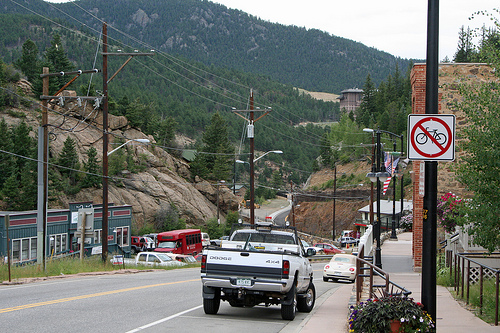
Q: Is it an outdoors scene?
A: Yes, it is outdoors.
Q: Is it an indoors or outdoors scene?
A: It is outdoors.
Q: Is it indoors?
A: No, it is outdoors.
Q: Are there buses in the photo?
A: Yes, there is a bus.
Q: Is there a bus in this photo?
A: Yes, there is a bus.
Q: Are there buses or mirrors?
A: Yes, there is a bus.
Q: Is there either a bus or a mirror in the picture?
A: Yes, there is a bus.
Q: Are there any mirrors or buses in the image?
A: Yes, there is a bus.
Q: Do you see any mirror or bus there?
A: Yes, there is a bus.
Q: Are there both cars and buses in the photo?
A: Yes, there are both a bus and a car.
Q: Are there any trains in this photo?
A: No, there are no trains.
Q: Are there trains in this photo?
A: No, there are no trains.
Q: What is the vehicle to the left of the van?
A: The vehicle is a bus.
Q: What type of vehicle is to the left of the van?
A: The vehicle is a bus.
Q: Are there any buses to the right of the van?
A: No, the bus is to the left of the van.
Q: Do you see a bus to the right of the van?
A: No, the bus is to the left of the van.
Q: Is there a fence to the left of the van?
A: No, there is a bus to the left of the van.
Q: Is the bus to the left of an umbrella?
A: No, the bus is to the left of a van.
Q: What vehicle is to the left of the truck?
A: The vehicle is a bus.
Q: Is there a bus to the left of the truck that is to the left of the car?
A: Yes, there is a bus to the left of the truck.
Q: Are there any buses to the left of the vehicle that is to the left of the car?
A: Yes, there is a bus to the left of the truck.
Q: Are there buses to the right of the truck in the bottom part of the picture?
A: No, the bus is to the left of the truck.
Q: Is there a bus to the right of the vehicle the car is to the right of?
A: No, the bus is to the left of the truck.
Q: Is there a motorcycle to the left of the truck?
A: No, there is a bus to the left of the truck.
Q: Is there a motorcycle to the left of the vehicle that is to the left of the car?
A: No, there is a bus to the left of the truck.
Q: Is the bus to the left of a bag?
A: No, the bus is to the left of the truck.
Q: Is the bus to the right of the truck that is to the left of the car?
A: No, the bus is to the left of the truck.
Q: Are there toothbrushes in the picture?
A: No, there are no toothbrushes.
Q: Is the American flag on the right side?
A: Yes, the American flag is on the right of the image.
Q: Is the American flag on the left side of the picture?
A: No, the American flag is on the right of the image.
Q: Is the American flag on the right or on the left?
A: The American flag is on the right of the image.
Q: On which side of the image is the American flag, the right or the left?
A: The American flag is on the right of the image.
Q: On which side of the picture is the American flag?
A: The American flag is on the right of the image.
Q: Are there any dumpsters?
A: No, there are no dumpsters.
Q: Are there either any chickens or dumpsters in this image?
A: No, there are no dumpsters or chickens.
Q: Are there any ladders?
A: No, there are no ladders.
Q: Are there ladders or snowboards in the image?
A: No, there are no ladders or snowboards.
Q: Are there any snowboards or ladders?
A: No, there are no ladders or snowboards.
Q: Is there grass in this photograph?
A: Yes, there is grass.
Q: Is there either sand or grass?
A: Yes, there is grass.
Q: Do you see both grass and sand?
A: No, there is grass but no sand.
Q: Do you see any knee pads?
A: No, there are no knee pads.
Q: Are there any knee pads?
A: No, there are no knee pads.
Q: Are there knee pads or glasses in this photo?
A: No, there are no knee pads or glasses.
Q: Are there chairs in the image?
A: No, there are no chairs.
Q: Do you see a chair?
A: No, there are no chairs.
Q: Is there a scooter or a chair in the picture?
A: No, there are no chairs or scooters.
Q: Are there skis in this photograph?
A: No, there are no skis.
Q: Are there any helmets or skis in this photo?
A: No, there are no skis or helmets.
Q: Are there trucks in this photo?
A: Yes, there is a truck.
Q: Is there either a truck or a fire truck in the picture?
A: Yes, there is a truck.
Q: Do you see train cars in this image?
A: No, there are no train cars.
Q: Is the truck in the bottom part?
A: Yes, the truck is in the bottom of the image.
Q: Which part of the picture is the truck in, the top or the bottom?
A: The truck is in the bottom of the image.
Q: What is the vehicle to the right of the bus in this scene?
A: The vehicle is a truck.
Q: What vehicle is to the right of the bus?
A: The vehicle is a truck.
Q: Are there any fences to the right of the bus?
A: No, there is a truck to the right of the bus.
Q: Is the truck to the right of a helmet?
A: No, the truck is to the right of a bus.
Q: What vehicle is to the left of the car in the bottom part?
A: The vehicle is a truck.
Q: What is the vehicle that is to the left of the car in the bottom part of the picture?
A: The vehicle is a truck.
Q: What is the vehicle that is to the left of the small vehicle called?
A: The vehicle is a truck.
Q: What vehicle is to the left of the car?
A: The vehicle is a truck.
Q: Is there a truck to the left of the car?
A: Yes, there is a truck to the left of the car.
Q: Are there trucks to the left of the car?
A: Yes, there is a truck to the left of the car.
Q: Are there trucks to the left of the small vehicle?
A: Yes, there is a truck to the left of the car.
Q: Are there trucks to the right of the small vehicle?
A: No, the truck is to the left of the car.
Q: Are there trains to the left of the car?
A: No, there is a truck to the left of the car.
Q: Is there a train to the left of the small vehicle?
A: No, there is a truck to the left of the car.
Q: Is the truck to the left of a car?
A: Yes, the truck is to the left of a car.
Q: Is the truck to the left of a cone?
A: No, the truck is to the left of a car.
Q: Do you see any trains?
A: No, there are no trains.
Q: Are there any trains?
A: No, there are no trains.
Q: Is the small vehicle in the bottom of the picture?
A: Yes, the car is in the bottom of the image.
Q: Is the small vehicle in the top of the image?
A: No, the car is in the bottom of the image.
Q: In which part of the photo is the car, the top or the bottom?
A: The car is in the bottom of the image.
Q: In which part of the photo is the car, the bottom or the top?
A: The car is in the bottom of the image.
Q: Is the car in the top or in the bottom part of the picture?
A: The car is in the bottom of the image.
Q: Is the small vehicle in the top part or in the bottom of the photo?
A: The car is in the bottom of the image.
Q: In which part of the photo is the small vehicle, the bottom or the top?
A: The car is in the bottom of the image.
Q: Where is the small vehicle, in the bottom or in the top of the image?
A: The car is in the bottom of the image.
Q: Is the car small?
A: Yes, the car is small.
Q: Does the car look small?
A: Yes, the car is small.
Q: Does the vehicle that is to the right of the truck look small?
A: Yes, the car is small.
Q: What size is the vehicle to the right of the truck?
A: The car is small.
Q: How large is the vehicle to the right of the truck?
A: The car is small.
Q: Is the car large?
A: No, the car is small.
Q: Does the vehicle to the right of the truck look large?
A: No, the car is small.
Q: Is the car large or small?
A: The car is small.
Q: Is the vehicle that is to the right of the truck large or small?
A: The car is small.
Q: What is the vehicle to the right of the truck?
A: The vehicle is a car.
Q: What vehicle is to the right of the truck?
A: The vehicle is a car.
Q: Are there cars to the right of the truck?
A: Yes, there is a car to the right of the truck.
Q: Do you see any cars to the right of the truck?
A: Yes, there is a car to the right of the truck.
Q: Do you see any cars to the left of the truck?
A: No, the car is to the right of the truck.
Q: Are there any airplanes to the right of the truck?
A: No, there is a car to the right of the truck.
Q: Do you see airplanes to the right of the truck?
A: No, there is a car to the right of the truck.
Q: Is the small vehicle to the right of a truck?
A: Yes, the car is to the right of a truck.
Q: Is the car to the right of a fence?
A: No, the car is to the right of a truck.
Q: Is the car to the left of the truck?
A: No, the car is to the right of the truck.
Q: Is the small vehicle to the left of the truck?
A: No, the car is to the right of the truck.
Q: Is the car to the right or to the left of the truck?
A: The car is to the right of the truck.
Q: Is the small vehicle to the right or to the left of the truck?
A: The car is to the right of the truck.